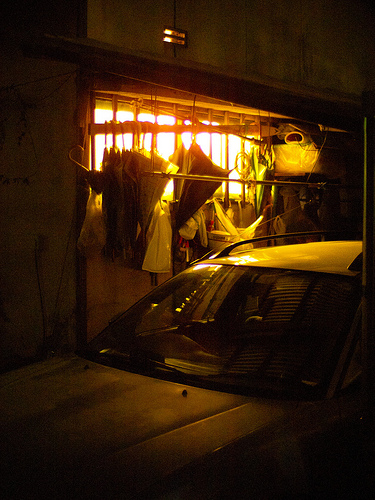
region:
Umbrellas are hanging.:
[73, 115, 236, 257]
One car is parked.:
[70, 244, 335, 474]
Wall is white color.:
[15, 138, 52, 232]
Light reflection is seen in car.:
[176, 240, 285, 315]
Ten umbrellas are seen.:
[73, 113, 225, 251]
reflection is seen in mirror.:
[140, 263, 329, 395]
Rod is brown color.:
[57, 34, 364, 134]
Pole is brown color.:
[354, 168, 372, 463]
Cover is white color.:
[135, 200, 176, 284]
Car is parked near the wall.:
[14, 259, 177, 388]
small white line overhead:
[139, 22, 215, 45]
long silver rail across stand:
[130, 158, 368, 209]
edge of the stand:
[113, 75, 220, 114]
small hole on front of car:
[169, 377, 218, 403]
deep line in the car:
[127, 395, 237, 446]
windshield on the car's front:
[226, 347, 322, 406]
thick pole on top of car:
[189, 222, 325, 252]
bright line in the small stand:
[122, 109, 260, 176]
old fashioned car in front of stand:
[52, 236, 340, 454]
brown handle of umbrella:
[41, 132, 121, 201]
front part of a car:
[135, 430, 178, 434]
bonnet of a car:
[157, 435, 182, 449]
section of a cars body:
[120, 453, 145, 476]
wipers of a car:
[239, 371, 259, 381]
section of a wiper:
[140, 358, 178, 370]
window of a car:
[244, 334, 267, 353]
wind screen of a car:
[196, 318, 221, 338]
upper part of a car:
[318, 262, 325, 268]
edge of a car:
[88, 331, 111, 349]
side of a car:
[291, 412, 320, 454]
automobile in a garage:
[0, 225, 371, 495]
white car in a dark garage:
[0, 2, 366, 487]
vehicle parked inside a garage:
[4, 150, 372, 498]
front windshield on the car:
[88, 261, 361, 401]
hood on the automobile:
[2, 354, 311, 499]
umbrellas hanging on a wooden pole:
[103, 118, 268, 268]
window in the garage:
[88, 101, 259, 199]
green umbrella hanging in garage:
[250, 120, 274, 214]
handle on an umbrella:
[65, 143, 102, 198]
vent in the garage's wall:
[160, 27, 188, 50]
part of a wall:
[271, 32, 309, 74]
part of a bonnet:
[141, 425, 186, 471]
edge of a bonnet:
[218, 437, 248, 469]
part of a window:
[248, 328, 288, 360]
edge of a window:
[225, 364, 259, 383]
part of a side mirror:
[346, 363, 364, 396]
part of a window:
[160, 326, 181, 356]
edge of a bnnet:
[23, 364, 70, 373]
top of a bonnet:
[81, 362, 129, 414]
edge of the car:
[240, 430, 281, 477]